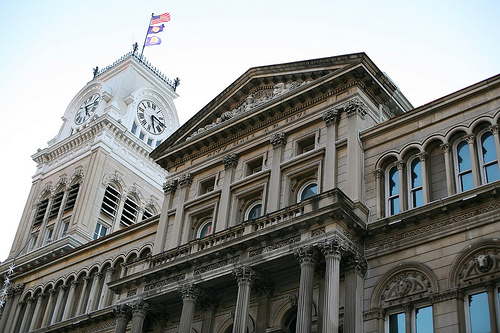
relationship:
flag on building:
[141, 10, 174, 48] [4, 42, 485, 318]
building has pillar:
[4, 42, 485, 318] [229, 264, 250, 333]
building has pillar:
[4, 42, 485, 318] [294, 252, 321, 332]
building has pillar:
[4, 42, 485, 318] [322, 253, 345, 333]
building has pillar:
[4, 42, 485, 318] [178, 292, 198, 332]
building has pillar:
[4, 42, 485, 318] [129, 304, 143, 332]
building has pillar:
[4, 42, 485, 318] [110, 304, 126, 332]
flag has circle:
[149, 24, 166, 32] [150, 24, 162, 35]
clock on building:
[134, 93, 167, 136] [4, 42, 485, 318]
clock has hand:
[134, 93, 167, 136] [151, 120, 157, 136]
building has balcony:
[4, 42, 485, 318] [105, 195, 366, 310]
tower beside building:
[0, 0, 500, 333] [4, 42, 485, 318]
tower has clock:
[0, 0, 500, 333] [134, 93, 167, 136]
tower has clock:
[0, 0, 500, 333] [70, 94, 99, 126]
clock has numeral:
[134, 93, 167, 136] [152, 101, 156, 111]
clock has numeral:
[134, 93, 167, 136] [144, 100, 154, 110]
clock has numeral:
[134, 93, 167, 136] [141, 103, 142, 109]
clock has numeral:
[134, 93, 167, 136] [147, 123, 153, 132]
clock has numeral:
[134, 93, 167, 136] [152, 122, 158, 135]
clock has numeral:
[134, 93, 167, 136] [141, 116, 148, 131]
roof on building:
[250, 52, 404, 94] [0, 0, 499, 333]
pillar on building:
[109, 300, 127, 330] [0, 85, 490, 330]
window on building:
[372, 148, 422, 211] [364, 76, 497, 326]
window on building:
[432, 95, 498, 198] [0, 0, 499, 333]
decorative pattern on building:
[367, 260, 441, 314] [0, 0, 499, 333]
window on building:
[90, 181, 175, 236] [36, 28, 184, 261]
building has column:
[4, 42, 485, 318] [110, 303, 130, 331]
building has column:
[4, 42, 485, 318] [129, 295, 150, 331]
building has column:
[4, 42, 485, 318] [175, 282, 202, 331]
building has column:
[4, 42, 485, 318] [231, 265, 257, 332]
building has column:
[4, 42, 485, 318] [293, 244, 318, 331]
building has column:
[4, 42, 485, 318] [319, 237, 344, 332]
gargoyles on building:
[379, 263, 436, 308] [4, 42, 485, 318]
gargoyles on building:
[372, 263, 437, 308] [4, 42, 485, 318]